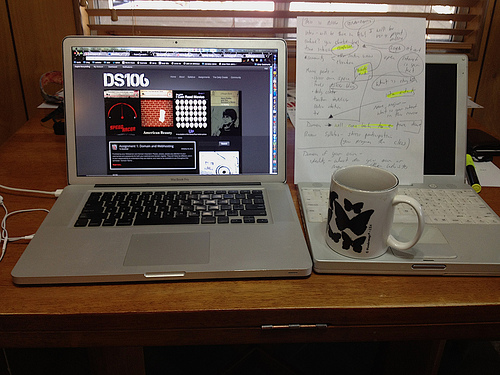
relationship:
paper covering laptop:
[294, 16, 425, 184] [300, 59, 499, 280]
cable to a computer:
[1, 196, 50, 263] [8, 34, 313, 289]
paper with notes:
[292, 16, 434, 181] [300, 17, 417, 169]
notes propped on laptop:
[300, 17, 417, 169] [5, 30, 317, 292]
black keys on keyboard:
[146, 195, 201, 216] [87, 187, 271, 224]